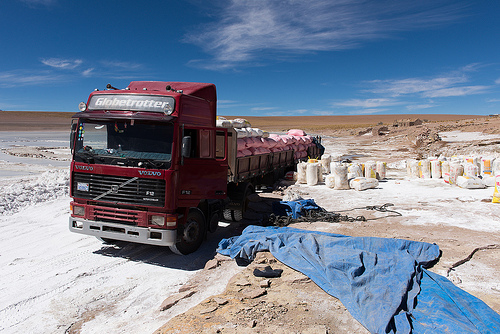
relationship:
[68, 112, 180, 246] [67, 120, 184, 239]
front of truck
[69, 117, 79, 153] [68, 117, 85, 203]
mirror on side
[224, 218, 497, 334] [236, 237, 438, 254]
tent has edge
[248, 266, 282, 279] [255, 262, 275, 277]
rock has part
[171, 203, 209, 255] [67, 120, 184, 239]
wheel on truck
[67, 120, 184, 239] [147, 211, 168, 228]
truck has headlight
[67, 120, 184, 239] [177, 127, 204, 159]
truck has window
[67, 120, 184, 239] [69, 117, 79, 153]
truck has mirror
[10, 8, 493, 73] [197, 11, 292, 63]
sky has cloud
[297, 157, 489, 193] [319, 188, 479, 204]
sand on ground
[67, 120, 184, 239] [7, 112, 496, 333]
truck in desert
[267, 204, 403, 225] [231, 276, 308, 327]
rope on ground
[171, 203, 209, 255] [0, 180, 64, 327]
wheels on sand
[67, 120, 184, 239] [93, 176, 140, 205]
truck has logo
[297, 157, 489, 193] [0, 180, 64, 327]
bags in sand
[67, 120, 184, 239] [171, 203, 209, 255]
truck has tire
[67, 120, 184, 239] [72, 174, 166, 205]
truck has grill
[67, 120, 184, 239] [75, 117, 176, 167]
truck has windshield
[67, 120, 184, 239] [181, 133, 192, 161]
truck has mirror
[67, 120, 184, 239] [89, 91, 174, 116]
truck has letters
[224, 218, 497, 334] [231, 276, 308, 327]
tarp on ground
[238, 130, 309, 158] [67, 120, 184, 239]
bags on truck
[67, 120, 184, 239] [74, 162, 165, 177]
truck says volvo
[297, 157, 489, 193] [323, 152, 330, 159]
bags filled with concrete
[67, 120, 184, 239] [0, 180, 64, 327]
truck on sand